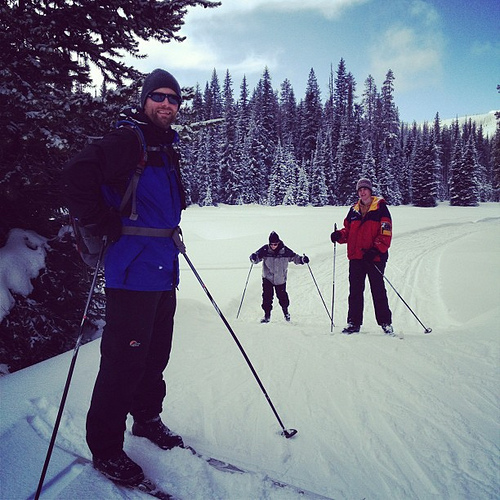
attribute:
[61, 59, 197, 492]
skiier — skiing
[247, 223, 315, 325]
skiier — skiing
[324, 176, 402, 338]
skiier — skiing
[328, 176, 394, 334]
people — skiing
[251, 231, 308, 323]
people — skiing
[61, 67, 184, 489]
people — skiing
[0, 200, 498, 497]
snow — white